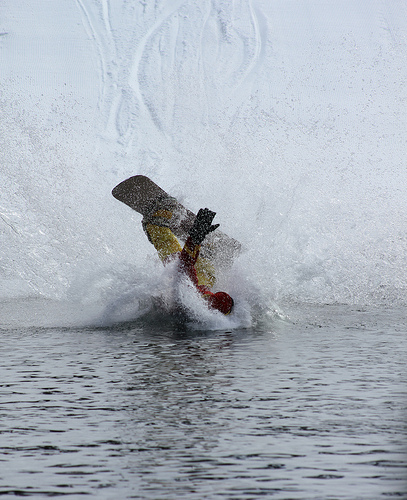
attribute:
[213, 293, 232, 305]
hat — red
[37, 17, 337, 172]
incline — covered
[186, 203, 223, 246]
glove — black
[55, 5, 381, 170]
water — elevated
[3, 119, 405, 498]
water — white, splashed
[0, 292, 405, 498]
water — calm, dark blue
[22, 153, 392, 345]
water — sprayed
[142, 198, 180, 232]
boots — black and yellow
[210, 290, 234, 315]
hat — red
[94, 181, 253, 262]
snowboard — brown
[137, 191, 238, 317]
man — falling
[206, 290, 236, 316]
hat — red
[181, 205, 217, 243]
glove — black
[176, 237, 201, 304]
sleeve — red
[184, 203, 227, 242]
gloves — black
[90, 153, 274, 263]
snowboard — black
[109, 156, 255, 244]
snowboard — yellow 